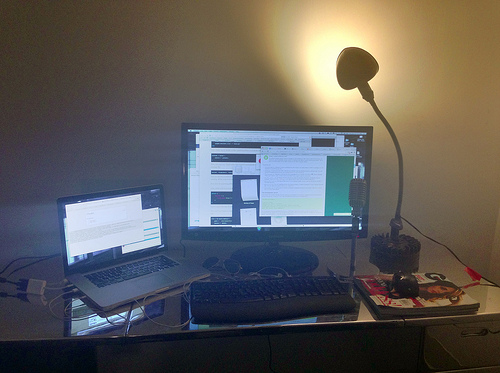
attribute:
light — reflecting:
[335, 45, 423, 273]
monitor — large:
[181, 123, 373, 274]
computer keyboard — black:
[187, 264, 353, 327]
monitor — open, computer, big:
[179, 118, 371, 242]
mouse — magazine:
[391, 271, 419, 294]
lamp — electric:
[331, 41, 385, 93]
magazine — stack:
[354, 269, 482, 319]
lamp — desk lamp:
[337, 46, 416, 268]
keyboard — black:
[192, 275, 354, 314]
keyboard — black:
[185, 274, 360, 322]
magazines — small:
[359, 269, 462, 314]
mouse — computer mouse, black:
[393, 271, 418, 296]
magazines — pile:
[358, 267, 455, 322]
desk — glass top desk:
[1, 227, 498, 371]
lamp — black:
[316, 31, 430, 321]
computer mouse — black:
[392, 272, 422, 297]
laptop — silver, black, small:
[55, 182, 211, 312]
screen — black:
[189, 127, 374, 240]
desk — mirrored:
[459, 284, 498, 315]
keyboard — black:
[186, 271, 417, 352]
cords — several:
[48, 280, 89, 315]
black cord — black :
[408, 225, 488, 287]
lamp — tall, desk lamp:
[324, 40, 424, 282]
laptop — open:
[48, 195, 204, 318]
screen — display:
[74, 195, 131, 233]